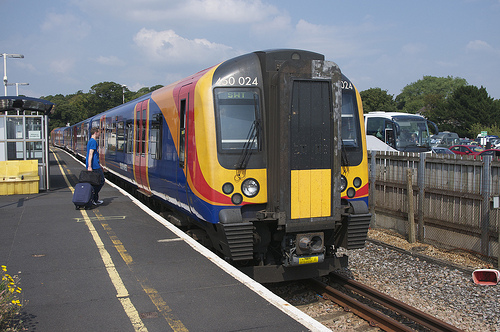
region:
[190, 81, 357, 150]
Windscreen of a train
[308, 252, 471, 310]
A railway track in the photo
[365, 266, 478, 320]
Track ballast in the photo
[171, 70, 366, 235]
A train on the railway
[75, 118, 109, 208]
A man in the photo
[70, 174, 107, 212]
A suitcase in the photo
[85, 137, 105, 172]
A blue t-shirt in the photo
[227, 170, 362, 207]
Headlights of a photo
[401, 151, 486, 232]
A fence in the photo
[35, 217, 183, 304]
A road with tarmac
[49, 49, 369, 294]
Train at the train station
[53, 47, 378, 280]
The train is black, yellow, red, blue and orange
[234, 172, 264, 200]
The light is round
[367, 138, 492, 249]
The fence is wood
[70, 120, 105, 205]
The man is carrying suit cases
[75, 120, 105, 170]
The man is wearing a blue shirt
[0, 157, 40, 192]
The wall is yellow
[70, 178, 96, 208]
The suit case is blue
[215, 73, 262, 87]
The numbers on the front of the train are white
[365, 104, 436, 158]
The bus is behind the fence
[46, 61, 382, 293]
A busy commuter train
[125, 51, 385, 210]
The commuter train is yellow red orange and blue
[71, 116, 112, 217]
A man in blue has two bags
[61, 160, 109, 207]
Two bags one black one blue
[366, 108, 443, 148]
A passenger bus drops off passengers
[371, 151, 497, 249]
A worn wooden fence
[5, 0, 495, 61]
A really cloudy sky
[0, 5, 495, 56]
A sunny blue day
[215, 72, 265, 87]
The trains number is 50 024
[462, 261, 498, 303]
An orange over turned cone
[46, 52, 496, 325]
a train on the tracks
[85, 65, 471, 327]
a passenger train on the tracks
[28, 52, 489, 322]
a train at a station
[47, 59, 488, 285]
a passenger train at the station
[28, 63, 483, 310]
a track with a train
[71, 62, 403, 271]
a track with a passenger train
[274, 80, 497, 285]
a wooden fence along the track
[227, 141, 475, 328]
train tracks next to sidewalk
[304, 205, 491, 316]
train tracks with rocks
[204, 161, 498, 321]
rocks around a track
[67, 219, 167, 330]
yellow lines painted on the pavement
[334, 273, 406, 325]
track for the train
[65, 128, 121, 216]
person with luggage boarding the train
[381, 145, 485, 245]
wooden fence behind the train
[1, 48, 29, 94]
street lights on the platform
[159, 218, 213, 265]
white line along the edge of the platform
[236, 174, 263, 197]
headlight on the train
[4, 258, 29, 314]
yellow flowers on the platform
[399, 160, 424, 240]
wooden post by the fence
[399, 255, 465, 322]
rocks by the tracks